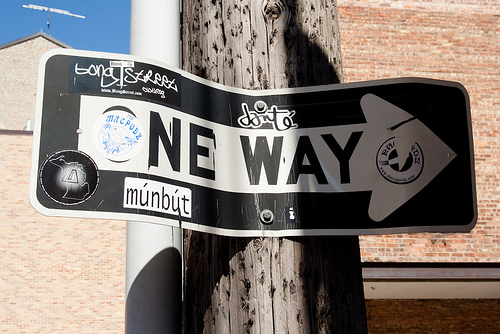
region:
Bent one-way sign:
[62, 41, 480, 258]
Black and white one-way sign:
[96, 78, 471, 249]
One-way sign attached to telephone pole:
[175, 30, 387, 327]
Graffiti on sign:
[57, 55, 183, 120]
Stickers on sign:
[15, 143, 195, 231]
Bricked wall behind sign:
[357, 62, 485, 254]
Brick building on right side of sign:
[0, 70, 183, 322]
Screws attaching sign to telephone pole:
[246, 85, 281, 235]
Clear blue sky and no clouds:
[77, 1, 127, 56]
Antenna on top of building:
[8, 3, 86, 47]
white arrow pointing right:
[351, 82, 474, 202]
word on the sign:
[227, 115, 372, 217]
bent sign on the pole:
[44, 91, 450, 251]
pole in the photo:
[186, 239, 376, 312]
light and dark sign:
[90, 67, 455, 234]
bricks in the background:
[354, 26, 416, 48]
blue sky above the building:
[95, 3, 118, 33]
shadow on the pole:
[110, 237, 187, 319]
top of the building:
[10, 25, 53, 57]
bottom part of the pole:
[176, 261, 395, 324]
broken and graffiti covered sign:
[26, 45, 481, 237]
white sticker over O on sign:
[88, 100, 148, 167]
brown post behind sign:
[182, 5, 369, 332]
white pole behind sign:
[125, 5, 180, 332]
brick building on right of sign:
[337, 1, 499, 260]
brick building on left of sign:
[1, 32, 127, 332]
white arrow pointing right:
[72, 91, 457, 219]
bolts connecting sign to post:
[251, 97, 276, 224]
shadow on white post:
[125, 242, 183, 332]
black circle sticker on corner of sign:
[36, 145, 98, 207]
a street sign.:
[23, 36, 483, 243]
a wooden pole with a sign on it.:
[170, 0, 380, 327]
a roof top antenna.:
[15, 0, 95, 48]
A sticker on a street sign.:
[108, 158, 198, 222]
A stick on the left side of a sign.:
[33, 146, 108, 208]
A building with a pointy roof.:
[0, 29, 130, 126]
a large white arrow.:
[53, 96, 460, 218]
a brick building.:
[338, 0, 498, 262]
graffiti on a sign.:
[49, 57, 182, 117]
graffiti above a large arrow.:
[205, 86, 309, 142]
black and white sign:
[64, 53, 469, 218]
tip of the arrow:
[342, 94, 459, 220]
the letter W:
[229, 125, 290, 195]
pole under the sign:
[207, 246, 321, 298]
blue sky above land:
[92, 9, 121, 37]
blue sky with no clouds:
[88, 3, 125, 35]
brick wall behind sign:
[392, 29, 451, 66]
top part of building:
[26, 21, 59, 50]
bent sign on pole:
[121, 81, 386, 217]